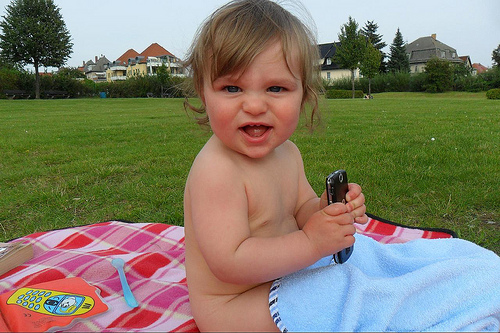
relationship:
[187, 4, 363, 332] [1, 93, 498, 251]
baby on grass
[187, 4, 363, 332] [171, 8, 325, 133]
baby has hair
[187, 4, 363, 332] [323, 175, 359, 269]
baby holding phone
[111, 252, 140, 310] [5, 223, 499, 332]
spoon on blanket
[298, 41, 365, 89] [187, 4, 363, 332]
house behind baby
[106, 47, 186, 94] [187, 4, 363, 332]
house behind baby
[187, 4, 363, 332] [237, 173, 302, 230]
baby has chest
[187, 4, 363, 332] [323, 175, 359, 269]
baby has phone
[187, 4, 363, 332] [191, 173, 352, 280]
baby has arm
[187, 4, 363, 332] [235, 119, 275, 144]
baby has mouth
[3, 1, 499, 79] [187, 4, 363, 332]
sky behind baby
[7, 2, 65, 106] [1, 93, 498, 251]
tree in grass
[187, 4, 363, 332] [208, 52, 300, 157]
baby has face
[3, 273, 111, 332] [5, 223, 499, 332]
toy on blanket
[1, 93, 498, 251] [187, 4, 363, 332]
grass behind baby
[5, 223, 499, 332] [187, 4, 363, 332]
blanket under baby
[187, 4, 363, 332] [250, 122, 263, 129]
baby has teeth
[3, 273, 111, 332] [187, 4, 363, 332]
toy for baby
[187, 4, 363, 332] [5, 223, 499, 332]
baby on blanket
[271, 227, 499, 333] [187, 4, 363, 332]
towel on baby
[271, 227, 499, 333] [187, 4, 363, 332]
towel covering baby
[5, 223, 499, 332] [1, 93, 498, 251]
blanket on grass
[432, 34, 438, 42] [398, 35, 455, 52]
chimney on roof